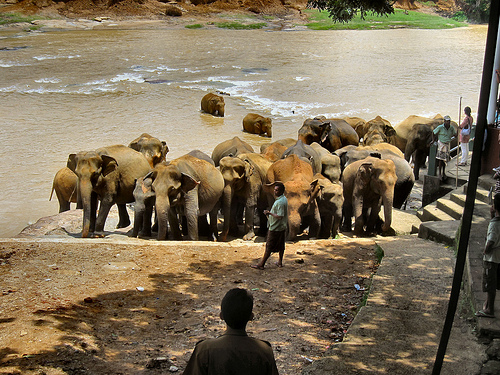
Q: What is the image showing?
A: It is showing a river.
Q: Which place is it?
A: It is a river.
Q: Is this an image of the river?
A: Yes, it is showing the river.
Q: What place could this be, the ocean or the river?
A: It is the river.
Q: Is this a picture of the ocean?
A: No, the picture is showing the river.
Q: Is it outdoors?
A: Yes, it is outdoors.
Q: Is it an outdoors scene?
A: Yes, it is outdoors.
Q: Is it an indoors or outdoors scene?
A: It is outdoors.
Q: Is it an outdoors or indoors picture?
A: It is outdoors.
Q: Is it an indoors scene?
A: No, it is outdoors.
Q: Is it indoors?
A: No, it is outdoors.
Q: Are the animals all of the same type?
A: Yes, all the animals are elephants.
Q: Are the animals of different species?
A: No, all the animals are elephants.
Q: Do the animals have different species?
A: No, all the animals are elephants.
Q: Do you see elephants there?
A: Yes, there are elephants.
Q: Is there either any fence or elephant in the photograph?
A: Yes, there are elephants.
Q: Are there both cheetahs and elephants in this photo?
A: No, there are elephants but no cheetahs.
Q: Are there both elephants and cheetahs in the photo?
A: No, there are elephants but no cheetahs.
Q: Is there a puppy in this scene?
A: No, there are no puppies.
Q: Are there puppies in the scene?
A: No, there are no puppies.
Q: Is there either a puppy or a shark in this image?
A: No, there are no puppies or sharks.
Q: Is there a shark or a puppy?
A: No, there are no puppies or sharks.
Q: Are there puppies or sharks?
A: No, there are no puppies or sharks.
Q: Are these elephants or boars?
A: These are elephants.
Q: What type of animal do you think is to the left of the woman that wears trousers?
A: The animals are elephants.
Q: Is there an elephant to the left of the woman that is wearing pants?
A: Yes, there are elephants to the left of the woman.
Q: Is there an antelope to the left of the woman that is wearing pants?
A: No, there are elephants to the left of the woman.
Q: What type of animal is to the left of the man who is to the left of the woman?
A: The animals are elephants.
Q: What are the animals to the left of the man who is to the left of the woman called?
A: The animals are elephants.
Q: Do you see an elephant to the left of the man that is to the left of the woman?
A: Yes, there are elephants to the left of the man.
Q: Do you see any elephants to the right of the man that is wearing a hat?
A: No, the elephants are to the left of the man.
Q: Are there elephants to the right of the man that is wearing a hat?
A: No, the elephants are to the left of the man.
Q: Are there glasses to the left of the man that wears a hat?
A: No, there are elephants to the left of the man.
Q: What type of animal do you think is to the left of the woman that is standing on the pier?
A: The animals are elephants.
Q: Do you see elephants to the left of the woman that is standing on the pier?
A: Yes, there are elephants to the left of the woman.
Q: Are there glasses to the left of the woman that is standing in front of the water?
A: No, there are elephants to the left of the woman.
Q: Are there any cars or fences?
A: No, there are no fences or cars.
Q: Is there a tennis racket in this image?
A: No, there are no rackets.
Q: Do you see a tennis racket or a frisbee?
A: No, there are no rackets or frisbees.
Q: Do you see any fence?
A: No, there are no fences.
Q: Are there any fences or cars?
A: No, there are no fences or cars.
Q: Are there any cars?
A: No, there are no cars.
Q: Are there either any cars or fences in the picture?
A: No, there are no cars or fences.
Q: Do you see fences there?
A: No, there are no fences.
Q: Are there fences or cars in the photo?
A: No, there are no fences or cars.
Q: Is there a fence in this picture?
A: No, there are no fences.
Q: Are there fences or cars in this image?
A: No, there are no fences or cars.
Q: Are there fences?
A: No, there are no fences.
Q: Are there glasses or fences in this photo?
A: No, there are no fences or glasses.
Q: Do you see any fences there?
A: No, there are no fences.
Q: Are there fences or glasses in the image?
A: No, there are no fences or glasses.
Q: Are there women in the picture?
A: Yes, there is a woman.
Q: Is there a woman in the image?
A: Yes, there is a woman.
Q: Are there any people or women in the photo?
A: Yes, there is a woman.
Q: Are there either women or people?
A: Yes, there is a woman.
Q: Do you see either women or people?
A: Yes, there is a woman.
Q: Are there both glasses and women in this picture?
A: No, there is a woman but no glasses.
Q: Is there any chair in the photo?
A: No, there are no chairs.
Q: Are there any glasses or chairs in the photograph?
A: No, there are no chairs or glasses.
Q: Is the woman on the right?
A: Yes, the woman is on the right of the image.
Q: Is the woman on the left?
A: No, the woman is on the right of the image.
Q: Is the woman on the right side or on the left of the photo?
A: The woman is on the right of the image.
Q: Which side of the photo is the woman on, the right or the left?
A: The woman is on the right of the image.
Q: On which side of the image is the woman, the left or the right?
A: The woman is on the right of the image.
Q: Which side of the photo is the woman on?
A: The woman is on the right of the image.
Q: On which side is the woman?
A: The woman is on the right of the image.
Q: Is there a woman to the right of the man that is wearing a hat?
A: Yes, there is a woman to the right of the man.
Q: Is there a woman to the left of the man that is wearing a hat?
A: No, the woman is to the right of the man.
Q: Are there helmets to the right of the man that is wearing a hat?
A: No, there is a woman to the right of the man.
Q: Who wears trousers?
A: The woman wears trousers.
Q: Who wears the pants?
A: The woman wears trousers.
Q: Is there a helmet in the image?
A: No, there are no helmets.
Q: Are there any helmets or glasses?
A: No, there are no helmets or glasses.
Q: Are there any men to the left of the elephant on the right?
A: Yes, there is a man to the left of the elephant.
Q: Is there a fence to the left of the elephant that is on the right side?
A: No, there is a man to the left of the elephant.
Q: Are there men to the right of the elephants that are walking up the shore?
A: Yes, there is a man to the right of the elephants.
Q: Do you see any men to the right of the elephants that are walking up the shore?
A: Yes, there is a man to the right of the elephants.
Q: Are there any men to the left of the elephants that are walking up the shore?
A: No, the man is to the right of the elephants.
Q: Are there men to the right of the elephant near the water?
A: Yes, there is a man to the right of the elephant.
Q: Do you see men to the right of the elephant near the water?
A: Yes, there is a man to the right of the elephant.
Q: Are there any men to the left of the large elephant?
A: No, the man is to the right of the elephant.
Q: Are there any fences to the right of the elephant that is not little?
A: No, there is a man to the right of the elephant.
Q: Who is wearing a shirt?
A: The man is wearing a shirt.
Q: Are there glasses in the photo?
A: No, there are no glasses.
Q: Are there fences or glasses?
A: No, there are no glasses or fences.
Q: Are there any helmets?
A: No, there are no helmets.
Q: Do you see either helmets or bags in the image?
A: No, there are no helmets or bags.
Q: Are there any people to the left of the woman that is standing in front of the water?
A: Yes, there is a person to the left of the woman.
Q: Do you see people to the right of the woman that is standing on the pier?
A: No, the person is to the left of the woman.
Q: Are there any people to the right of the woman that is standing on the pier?
A: No, the person is to the left of the woman.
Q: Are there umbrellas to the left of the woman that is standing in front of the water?
A: No, there is a person to the left of the woman.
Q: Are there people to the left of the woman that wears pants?
A: Yes, there is a person to the left of the woman.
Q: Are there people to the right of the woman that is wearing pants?
A: No, the person is to the left of the woman.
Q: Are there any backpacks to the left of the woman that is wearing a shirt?
A: No, there is a person to the left of the woman.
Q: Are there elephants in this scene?
A: Yes, there is an elephant.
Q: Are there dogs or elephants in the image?
A: Yes, there is an elephant.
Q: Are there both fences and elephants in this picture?
A: No, there is an elephant but no fences.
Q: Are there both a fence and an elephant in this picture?
A: No, there is an elephant but no fences.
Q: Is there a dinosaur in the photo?
A: No, there are no dinosaurs.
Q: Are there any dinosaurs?
A: No, there are no dinosaurs.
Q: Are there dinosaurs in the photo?
A: No, there are no dinosaurs.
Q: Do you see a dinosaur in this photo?
A: No, there are no dinosaurs.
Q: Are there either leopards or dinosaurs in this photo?
A: No, there are no dinosaurs or leopards.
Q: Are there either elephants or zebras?
A: Yes, there is an elephant.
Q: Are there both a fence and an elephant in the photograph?
A: No, there is an elephant but no fences.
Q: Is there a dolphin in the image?
A: No, there are no dolphins.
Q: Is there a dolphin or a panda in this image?
A: No, there are no dolphins or pandas.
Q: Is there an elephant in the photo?
A: Yes, there is an elephant.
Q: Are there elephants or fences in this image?
A: Yes, there is an elephant.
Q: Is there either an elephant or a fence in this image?
A: Yes, there is an elephant.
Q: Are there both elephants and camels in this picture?
A: No, there is an elephant but no camels.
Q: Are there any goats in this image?
A: No, there are no goats.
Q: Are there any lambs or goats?
A: No, there are no goats or lambs.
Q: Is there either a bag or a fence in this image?
A: No, there are no fences or bags.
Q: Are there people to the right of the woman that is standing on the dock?
A: No, the person is to the left of the woman.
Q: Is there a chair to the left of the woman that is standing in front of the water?
A: No, there is a person to the left of the woman.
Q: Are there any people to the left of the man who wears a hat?
A: Yes, there is a person to the left of the man.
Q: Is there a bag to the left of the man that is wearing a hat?
A: No, there is a person to the left of the man.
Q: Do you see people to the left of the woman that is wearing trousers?
A: Yes, there is a person to the left of the woman.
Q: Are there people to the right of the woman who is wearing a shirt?
A: No, the person is to the left of the woman.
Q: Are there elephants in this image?
A: Yes, there is an elephant.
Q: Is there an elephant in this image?
A: Yes, there is an elephant.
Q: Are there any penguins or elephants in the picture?
A: Yes, there is an elephant.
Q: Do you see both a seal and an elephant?
A: No, there is an elephant but no seals.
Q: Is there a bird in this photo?
A: No, there are no birds.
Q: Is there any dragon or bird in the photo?
A: No, there are no birds or dragons.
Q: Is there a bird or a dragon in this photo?
A: No, there are no birds or dragons.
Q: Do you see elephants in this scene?
A: Yes, there are elephants.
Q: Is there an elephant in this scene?
A: Yes, there are elephants.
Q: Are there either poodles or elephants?
A: Yes, there are elephants.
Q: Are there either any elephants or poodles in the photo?
A: Yes, there are elephants.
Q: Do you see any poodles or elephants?
A: Yes, there are elephants.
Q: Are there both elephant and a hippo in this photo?
A: No, there are elephants but no hippos.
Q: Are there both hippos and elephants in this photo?
A: No, there are elephants but no hippos.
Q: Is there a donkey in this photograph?
A: No, there are no donkeys.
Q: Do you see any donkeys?
A: No, there are no donkeys.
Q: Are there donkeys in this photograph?
A: No, there are no donkeys.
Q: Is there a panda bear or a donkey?
A: No, there are no donkeys or pandas.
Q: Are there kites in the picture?
A: No, there are no kites.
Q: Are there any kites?
A: No, there are no kites.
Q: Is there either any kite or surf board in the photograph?
A: No, there are no kites or surfboards.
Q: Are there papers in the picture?
A: No, there are no papers.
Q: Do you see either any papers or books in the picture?
A: No, there are no papers or books.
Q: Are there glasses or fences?
A: No, there are no fences or glasses.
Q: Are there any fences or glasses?
A: No, there are no fences or glasses.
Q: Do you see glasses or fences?
A: No, there are no fences or glasses.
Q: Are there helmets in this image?
A: No, there are no helmets.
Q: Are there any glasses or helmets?
A: No, there are no helmets or glasses.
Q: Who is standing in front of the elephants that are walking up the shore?
A: The man is standing in front of the elephants.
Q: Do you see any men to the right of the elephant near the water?
A: Yes, there is a man to the right of the elephant.